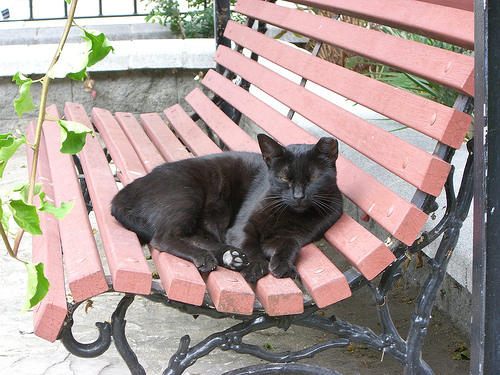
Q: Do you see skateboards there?
A: No, there are no skateboards.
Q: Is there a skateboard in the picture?
A: No, there are no skateboards.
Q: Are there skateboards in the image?
A: No, there are no skateboards.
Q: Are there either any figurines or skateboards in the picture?
A: No, there are no skateboards or figurines.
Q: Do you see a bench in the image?
A: Yes, there is a bench.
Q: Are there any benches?
A: Yes, there is a bench.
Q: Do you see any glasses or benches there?
A: Yes, there is a bench.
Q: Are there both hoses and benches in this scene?
A: No, there is a bench but no hoses.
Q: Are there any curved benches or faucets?
A: Yes, there is a curved bench.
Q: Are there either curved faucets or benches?
A: Yes, there is a curved bench.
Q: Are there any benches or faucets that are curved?
A: Yes, the bench is curved.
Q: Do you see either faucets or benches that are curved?
A: Yes, the bench is curved.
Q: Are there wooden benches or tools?
A: Yes, there is a wood bench.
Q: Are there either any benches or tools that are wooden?
A: Yes, the bench is wooden.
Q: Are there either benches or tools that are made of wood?
A: Yes, the bench is made of wood.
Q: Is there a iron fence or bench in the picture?
A: Yes, there is an iron bench.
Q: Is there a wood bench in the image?
A: Yes, there is a wood bench.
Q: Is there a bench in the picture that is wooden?
A: Yes, there is a bench that is wooden.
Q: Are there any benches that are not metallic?
A: Yes, there is a wooden bench.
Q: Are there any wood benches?
A: Yes, there is a bench that is made of wood.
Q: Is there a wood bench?
A: Yes, there is a bench that is made of wood.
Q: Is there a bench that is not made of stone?
A: Yes, there is a bench that is made of wood.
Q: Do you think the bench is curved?
A: Yes, the bench is curved.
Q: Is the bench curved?
A: Yes, the bench is curved.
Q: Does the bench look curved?
A: Yes, the bench is curved.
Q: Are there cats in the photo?
A: Yes, there is a cat.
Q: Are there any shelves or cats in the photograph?
A: Yes, there is a cat.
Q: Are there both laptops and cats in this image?
A: No, there is a cat but no laptops.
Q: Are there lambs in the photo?
A: No, there are no lambs.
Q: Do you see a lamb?
A: No, there are no lambs.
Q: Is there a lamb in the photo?
A: No, there are no lambs.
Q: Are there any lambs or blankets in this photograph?
A: No, there are no lambs or blankets.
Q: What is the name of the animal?
A: The animal is a cat.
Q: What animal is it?
A: The animal is a cat.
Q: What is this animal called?
A: This is a cat.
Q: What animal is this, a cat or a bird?
A: This is a cat.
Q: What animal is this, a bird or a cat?
A: This is a cat.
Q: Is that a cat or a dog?
A: That is a cat.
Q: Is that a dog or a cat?
A: That is a cat.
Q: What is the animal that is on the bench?
A: The animal is a cat.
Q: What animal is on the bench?
A: The animal is a cat.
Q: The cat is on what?
A: The cat is on the bench.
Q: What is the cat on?
A: The cat is on the bench.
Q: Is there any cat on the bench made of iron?
A: Yes, there is a cat on the bench.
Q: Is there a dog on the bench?
A: No, there is a cat on the bench.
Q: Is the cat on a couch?
A: No, the cat is on the bench.